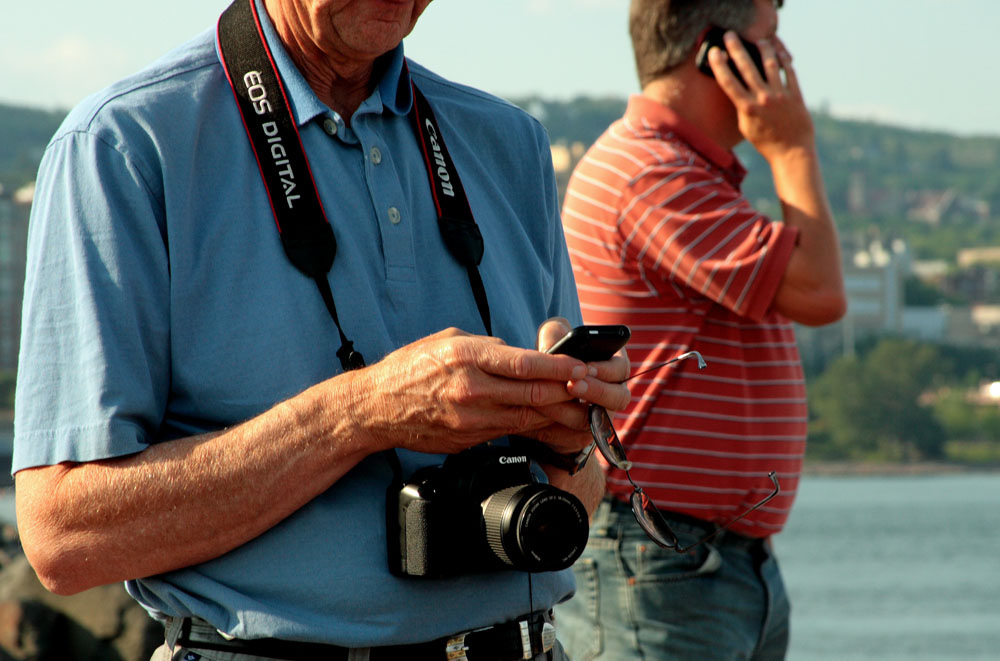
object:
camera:
[389, 452, 590, 577]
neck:
[263, 0, 373, 128]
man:
[10, 0, 632, 661]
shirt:
[10, 0, 584, 649]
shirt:
[560, 93, 808, 537]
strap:
[215, 0, 491, 473]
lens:
[484, 484, 531, 565]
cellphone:
[696, 42, 783, 88]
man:
[551, 0, 845, 660]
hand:
[376, 318, 631, 454]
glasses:
[587, 351, 780, 553]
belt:
[165, 617, 555, 660]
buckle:
[446, 621, 556, 661]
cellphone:
[545, 325, 632, 364]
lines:
[559, 118, 808, 539]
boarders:
[214, 0, 338, 280]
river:
[770, 469, 999, 661]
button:
[589, 331, 598, 334]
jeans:
[551, 497, 789, 661]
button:
[370, 148, 382, 165]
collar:
[253, 1, 413, 128]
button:
[324, 119, 337, 134]